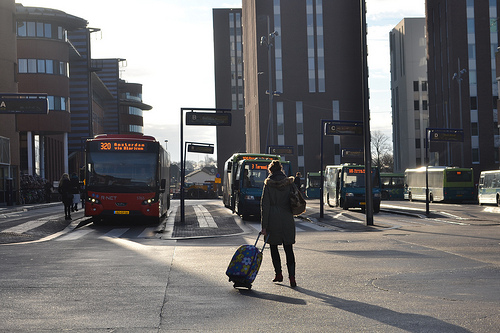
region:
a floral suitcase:
[223, 237, 266, 292]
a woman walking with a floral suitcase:
[222, 158, 314, 295]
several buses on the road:
[74, 128, 486, 229]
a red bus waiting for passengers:
[81, 129, 176, 227]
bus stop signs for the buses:
[0, 90, 470, 155]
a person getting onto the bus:
[53, 170, 78, 221]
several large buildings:
[4, 0, 496, 192]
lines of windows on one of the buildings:
[268, 3, 355, 183]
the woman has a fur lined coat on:
[254, 176, 311, 243]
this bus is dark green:
[399, 163, 473, 205]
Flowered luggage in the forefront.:
[225, 228, 270, 293]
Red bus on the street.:
[81, 133, 168, 230]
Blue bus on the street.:
[322, 160, 384, 213]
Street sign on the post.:
[181, 108, 233, 130]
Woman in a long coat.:
[258, 160, 309, 287]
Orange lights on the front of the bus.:
[95, 140, 147, 153]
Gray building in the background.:
[385, 20, 430, 170]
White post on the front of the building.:
[25, 130, 35, 178]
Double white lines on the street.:
[186, 200, 217, 231]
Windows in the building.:
[13, 15, 69, 41]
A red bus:
[77, 118, 173, 235]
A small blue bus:
[234, 156, 289, 221]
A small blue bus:
[319, 158, 384, 212]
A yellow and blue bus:
[399, 159, 473, 206]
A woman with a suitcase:
[222, 155, 316, 290]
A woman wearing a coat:
[251, 153, 319, 288]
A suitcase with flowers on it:
[223, 225, 270, 290]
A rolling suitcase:
[221, 219, 274, 292]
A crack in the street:
[143, 240, 179, 330]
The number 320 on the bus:
[94, 136, 112, 151]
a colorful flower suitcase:
[223, 230, 274, 289]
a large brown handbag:
[288, 175, 309, 214]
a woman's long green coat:
[253, 174, 297, 243]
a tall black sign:
[178, 102, 235, 232]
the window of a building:
[306, 56, 316, 70]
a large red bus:
[81, 120, 172, 225]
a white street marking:
[301, 212, 331, 239]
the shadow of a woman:
[282, 273, 468, 331]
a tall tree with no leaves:
[372, 130, 390, 166]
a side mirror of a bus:
[158, 176, 170, 192]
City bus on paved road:
[82, 115, 180, 235]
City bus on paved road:
[248, 164, 285, 219]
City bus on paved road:
[324, 153, 385, 216]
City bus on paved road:
[206, 143, 236, 210]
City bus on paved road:
[402, 156, 472, 206]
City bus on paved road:
[475, 173, 499, 207]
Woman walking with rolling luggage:
[230, 153, 308, 303]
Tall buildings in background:
[220, 10, 370, 165]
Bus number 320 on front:
[98, 138, 113, 153]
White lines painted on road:
[18, 200, 91, 252]